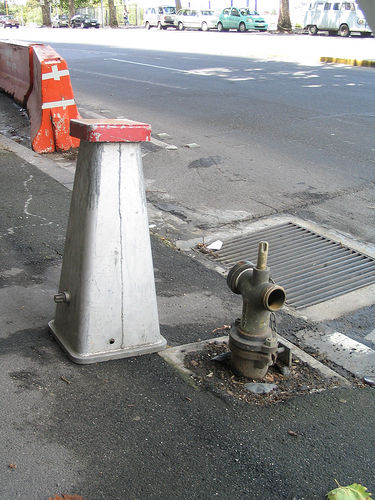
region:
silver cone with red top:
[45, 114, 173, 359]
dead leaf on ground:
[323, 478, 371, 499]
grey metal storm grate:
[185, 219, 374, 310]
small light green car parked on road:
[215, 5, 270, 32]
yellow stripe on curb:
[317, 55, 374, 68]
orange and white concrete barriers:
[1, 38, 85, 155]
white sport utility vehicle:
[170, 5, 218, 31]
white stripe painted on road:
[105, 52, 211, 85]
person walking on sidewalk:
[121, 6, 133, 26]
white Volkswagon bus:
[302, 3, 371, 39]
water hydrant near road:
[186, 134, 364, 397]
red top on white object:
[42, 103, 181, 363]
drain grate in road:
[174, 37, 366, 327]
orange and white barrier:
[2, 33, 127, 157]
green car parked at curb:
[212, 1, 283, 35]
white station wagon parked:
[166, 4, 265, 49]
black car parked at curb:
[60, 8, 137, 36]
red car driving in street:
[2, 0, 109, 63]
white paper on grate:
[193, 209, 304, 295]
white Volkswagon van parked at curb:
[285, 0, 373, 51]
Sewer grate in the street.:
[196, 210, 366, 321]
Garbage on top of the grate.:
[187, 232, 244, 257]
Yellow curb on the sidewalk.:
[308, 56, 370, 66]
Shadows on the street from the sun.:
[176, 68, 345, 88]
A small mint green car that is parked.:
[215, 7, 276, 31]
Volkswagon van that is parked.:
[289, 3, 352, 38]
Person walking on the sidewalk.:
[115, 7, 132, 29]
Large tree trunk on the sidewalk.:
[101, 1, 120, 27]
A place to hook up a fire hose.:
[196, 243, 296, 369]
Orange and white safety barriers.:
[15, 43, 88, 159]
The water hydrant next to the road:
[212, 234, 297, 380]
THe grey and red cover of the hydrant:
[37, 108, 181, 365]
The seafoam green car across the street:
[217, 3, 271, 34]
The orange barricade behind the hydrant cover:
[0, 37, 94, 151]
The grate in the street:
[201, 214, 374, 317]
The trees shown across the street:
[1, 0, 295, 32]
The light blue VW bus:
[296, 0, 371, 34]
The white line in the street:
[102, 51, 202, 75]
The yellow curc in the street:
[321, 47, 374, 74]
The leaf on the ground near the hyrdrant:
[310, 465, 374, 498]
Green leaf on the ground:
[323, 476, 374, 499]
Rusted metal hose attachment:
[222, 238, 293, 379]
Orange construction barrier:
[0, 38, 85, 154]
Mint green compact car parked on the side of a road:
[215, 5, 266, 33]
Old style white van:
[302, 0, 373, 37]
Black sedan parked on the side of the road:
[69, 14, 99, 30]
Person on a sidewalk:
[120, 6, 131, 26]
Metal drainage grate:
[197, 220, 373, 310]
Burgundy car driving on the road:
[0, 11, 20, 29]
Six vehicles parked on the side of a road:
[48, 0, 374, 35]